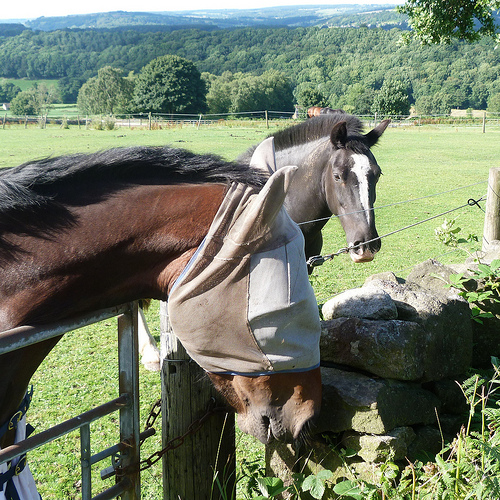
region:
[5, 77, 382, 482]
horses in the field with fence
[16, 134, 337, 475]
a horse wearing fly mask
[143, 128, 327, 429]
a horse fly mask with ears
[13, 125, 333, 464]
a brown horse with fly mask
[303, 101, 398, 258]
a black and white horse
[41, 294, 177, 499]
a gate of the fence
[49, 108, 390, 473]
two horses with the brown horse has a fly mask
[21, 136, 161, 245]
crest of the brown horse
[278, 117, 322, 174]
crest of the black horse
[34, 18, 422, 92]
panoramic view of the trees in the background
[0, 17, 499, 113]
trees in the background.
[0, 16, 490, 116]
the trees are green.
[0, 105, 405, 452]
two horses at the fence.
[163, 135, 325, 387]
horse is wearing a mask.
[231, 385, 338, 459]
the horse is eating.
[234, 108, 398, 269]
the horse is brown.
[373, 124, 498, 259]
the grass is green.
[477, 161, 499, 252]
the post is wooden.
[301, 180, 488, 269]
the wire is silver.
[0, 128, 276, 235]
horses mane is black.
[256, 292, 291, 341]
part of a cloth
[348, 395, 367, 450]
edge of a rock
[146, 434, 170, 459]
part of a chain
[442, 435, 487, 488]
part of a plant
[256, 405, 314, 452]
part of a mouth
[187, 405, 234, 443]
part of a chain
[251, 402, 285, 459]
edge of a horse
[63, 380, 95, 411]
part of a green field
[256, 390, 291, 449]
part of a horse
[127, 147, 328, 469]
a horse with a cover over its face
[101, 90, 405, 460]
two horses standing next to a fence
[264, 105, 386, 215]
a horse with a short mane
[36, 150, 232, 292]
a horse with a black mane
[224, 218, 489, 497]
a wall built of rocks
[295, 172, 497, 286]
wire cables attached to fence post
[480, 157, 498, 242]
a wooden fence post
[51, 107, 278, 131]
several wooden fence post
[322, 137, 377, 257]
a horse with white on its face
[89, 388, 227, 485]
a chain wrapped around a fence post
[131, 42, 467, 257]
the horse has ears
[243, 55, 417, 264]
the horse has ears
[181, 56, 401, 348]
the horse has ears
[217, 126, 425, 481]
the horse has ears